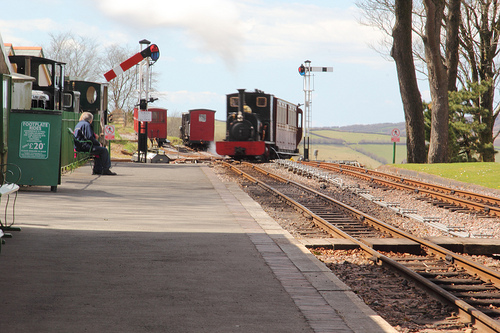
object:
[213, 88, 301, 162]
train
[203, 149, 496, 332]
tracks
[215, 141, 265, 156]
bumper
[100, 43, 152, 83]
train sign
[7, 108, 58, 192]
trash can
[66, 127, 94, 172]
bench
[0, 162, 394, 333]
platform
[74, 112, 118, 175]
man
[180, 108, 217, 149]
train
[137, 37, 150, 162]
pole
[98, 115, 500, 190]
field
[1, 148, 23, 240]
bench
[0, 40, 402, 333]
train station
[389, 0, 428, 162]
tree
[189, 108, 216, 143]
rear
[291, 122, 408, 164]
hill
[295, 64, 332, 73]
train sign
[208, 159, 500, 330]
gravel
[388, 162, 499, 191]
grass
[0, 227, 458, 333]
shadow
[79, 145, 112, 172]
pants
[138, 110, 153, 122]
sign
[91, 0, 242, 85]
smoke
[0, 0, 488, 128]
sky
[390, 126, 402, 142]
sign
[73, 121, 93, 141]
shirt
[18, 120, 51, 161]
ticket sign